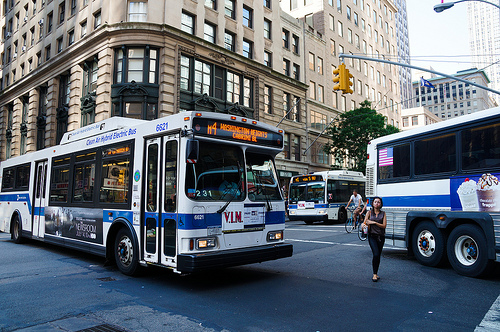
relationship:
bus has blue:
[1, 115, 298, 276] [269, 213, 284, 223]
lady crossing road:
[362, 197, 388, 282] [0, 199, 499, 332]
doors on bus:
[146, 128, 179, 266] [1, 115, 298, 276]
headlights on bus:
[196, 225, 283, 256] [1, 115, 298, 276]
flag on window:
[373, 148, 394, 166] [377, 139, 414, 184]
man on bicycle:
[343, 183, 369, 235] [344, 211, 367, 234]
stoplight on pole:
[331, 65, 354, 93] [336, 48, 498, 105]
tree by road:
[329, 108, 392, 162] [0, 199, 499, 332]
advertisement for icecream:
[434, 165, 499, 219] [458, 179, 495, 198]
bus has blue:
[364, 113, 499, 279] [397, 196, 408, 208]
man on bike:
[346, 190, 365, 226] [335, 210, 378, 243]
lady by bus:
[360, 198, 391, 279] [364, 113, 499, 279]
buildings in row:
[101, 7, 456, 107] [223, 76, 480, 109]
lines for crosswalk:
[293, 222, 308, 253] [269, 216, 405, 251]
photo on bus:
[434, 165, 499, 219] [364, 113, 499, 279]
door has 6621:
[146, 128, 179, 266] [141, 110, 182, 136]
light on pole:
[431, 0, 453, 23] [336, 48, 498, 105]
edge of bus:
[23, 143, 72, 159] [1, 115, 298, 276]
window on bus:
[55, 164, 72, 201] [1, 115, 298, 276]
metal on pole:
[490, 1, 495, 11] [466, 1, 493, 18]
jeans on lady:
[364, 233, 384, 273] [362, 197, 388, 282]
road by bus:
[18, 260, 144, 322] [1, 115, 298, 276]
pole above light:
[455, 1, 493, 8] [333, 69, 339, 95]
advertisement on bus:
[434, 165, 499, 219] [1, 115, 298, 276]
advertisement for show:
[37, 195, 111, 251] [70, 216, 107, 243]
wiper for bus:
[214, 184, 242, 211] [1, 115, 298, 276]